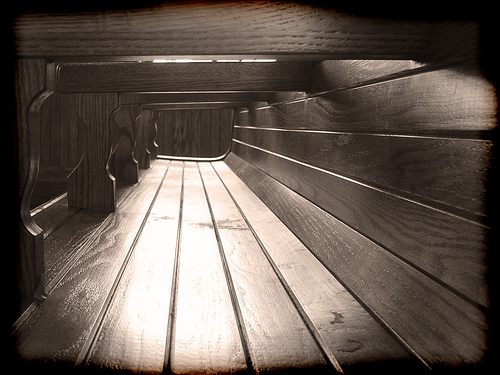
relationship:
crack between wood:
[162, 159, 187, 371] [161, 195, 171, 269]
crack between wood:
[193, 159, 256, 367] [192, 271, 228, 356]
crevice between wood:
[353, 227, 389, 250] [235, 236, 251, 279]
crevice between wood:
[371, 178, 438, 208] [239, 194, 253, 209]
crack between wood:
[207, 161, 347, 373] [275, 190, 294, 213]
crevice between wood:
[395, 125, 476, 150] [275, 190, 294, 213]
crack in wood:
[207, 161, 347, 373] [0, 1, 492, 371]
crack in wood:
[193, 159, 256, 367] [0, 1, 492, 371]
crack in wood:
[162, 159, 187, 371] [0, 1, 492, 371]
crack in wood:
[78, 159, 173, 366] [0, 1, 492, 371]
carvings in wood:
[148, 167, 282, 285] [152, 147, 361, 372]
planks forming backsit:
[224, 32, 498, 372] [225, 84, 484, 360]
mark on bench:
[115, 200, 247, 234] [16, 0, 497, 374]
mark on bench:
[325, 300, 360, 345] [96, 87, 465, 373]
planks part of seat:
[212, 75, 482, 359] [3, 2, 498, 109]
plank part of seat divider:
[64, 92, 120, 212] [14, 7, 475, 343]